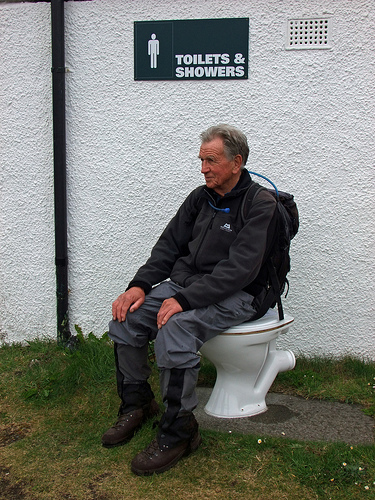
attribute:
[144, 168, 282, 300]
jacket — black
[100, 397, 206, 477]
shoes — brown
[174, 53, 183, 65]
letter — white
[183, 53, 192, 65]
letter — white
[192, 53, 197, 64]
letter — white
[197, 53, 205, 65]
letter — white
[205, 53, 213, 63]
letter — white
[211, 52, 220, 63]
letter — white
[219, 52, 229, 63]
letter — white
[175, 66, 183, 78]
letter — white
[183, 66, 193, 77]
letter — white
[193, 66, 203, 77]
letter — white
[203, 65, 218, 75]
letter — white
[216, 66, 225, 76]
letter — white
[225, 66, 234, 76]
letter — white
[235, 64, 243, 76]
letter — white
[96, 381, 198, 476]
boots — brown, lace-up, leather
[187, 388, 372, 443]
concrete pad — small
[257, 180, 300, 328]
backpack — black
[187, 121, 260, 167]
graying hair — gray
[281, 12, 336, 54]
vent — white , wall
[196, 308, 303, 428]
toilet — white and porcelain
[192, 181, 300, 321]
backpack — dark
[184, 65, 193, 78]
letter — white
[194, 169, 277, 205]
microphone — blue 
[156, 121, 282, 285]
man — elderly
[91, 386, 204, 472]
boots — brown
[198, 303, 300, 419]
toilet — outdoor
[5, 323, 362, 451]
lawn — bare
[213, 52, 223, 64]
letter — white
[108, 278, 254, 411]
pants — gray